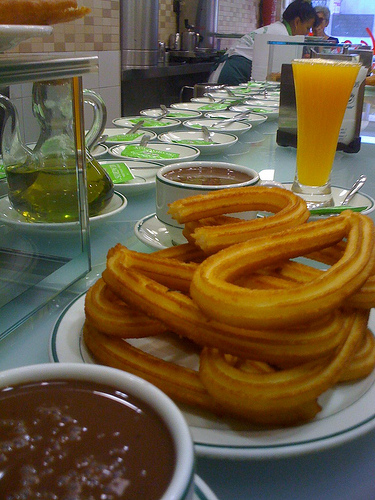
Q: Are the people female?
A: Yes, all the people are female.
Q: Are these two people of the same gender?
A: Yes, all the people are female.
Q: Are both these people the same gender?
A: Yes, all the people are female.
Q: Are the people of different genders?
A: No, all the people are female.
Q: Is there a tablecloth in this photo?
A: No, there are no tablecloths.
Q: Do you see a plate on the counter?
A: Yes, there are plates on the counter.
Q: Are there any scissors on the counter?
A: No, there are plates on the counter.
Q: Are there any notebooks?
A: No, there are no notebooks.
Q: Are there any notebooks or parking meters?
A: No, there are no notebooks or parking meters.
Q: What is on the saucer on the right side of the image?
A: The glass is on the saucer.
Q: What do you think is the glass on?
A: The glass is on the saucer.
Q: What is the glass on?
A: The glass is on the saucer.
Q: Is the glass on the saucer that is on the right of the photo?
A: Yes, the glass is on the saucer.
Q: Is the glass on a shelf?
A: No, the glass is on the saucer.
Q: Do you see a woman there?
A: Yes, there is a woman.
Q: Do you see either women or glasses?
A: Yes, there is a woman.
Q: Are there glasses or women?
A: Yes, there is a woman.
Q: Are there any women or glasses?
A: Yes, there is a woman.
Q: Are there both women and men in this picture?
A: No, there is a woman but no men.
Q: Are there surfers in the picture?
A: No, there are no surfers.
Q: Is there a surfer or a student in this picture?
A: No, there are no surfers or students.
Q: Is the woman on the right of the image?
A: Yes, the woman is on the right of the image.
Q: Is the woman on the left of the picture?
A: No, the woman is on the right of the image.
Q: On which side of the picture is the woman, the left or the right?
A: The woman is on the right of the image.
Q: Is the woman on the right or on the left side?
A: The woman is on the right of the image.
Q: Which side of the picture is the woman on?
A: The woman is on the right of the image.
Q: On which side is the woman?
A: The woman is on the right of the image.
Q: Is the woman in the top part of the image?
A: Yes, the woman is in the top of the image.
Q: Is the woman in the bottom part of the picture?
A: No, the woman is in the top of the image.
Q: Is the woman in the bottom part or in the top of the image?
A: The woman is in the top of the image.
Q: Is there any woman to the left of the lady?
A: Yes, there is a woman to the left of the lady.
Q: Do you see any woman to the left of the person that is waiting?
A: Yes, there is a woman to the left of the lady.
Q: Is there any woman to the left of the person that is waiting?
A: Yes, there is a woman to the left of the lady.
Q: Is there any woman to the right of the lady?
A: No, the woman is to the left of the lady.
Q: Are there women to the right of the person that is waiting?
A: No, the woman is to the left of the lady.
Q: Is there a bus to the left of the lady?
A: No, there is a woman to the left of the lady.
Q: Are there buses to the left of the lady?
A: No, there is a woman to the left of the lady.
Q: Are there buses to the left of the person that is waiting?
A: No, there is a woman to the left of the lady.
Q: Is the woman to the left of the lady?
A: Yes, the woman is to the left of the lady.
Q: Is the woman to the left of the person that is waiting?
A: Yes, the woman is to the left of the lady.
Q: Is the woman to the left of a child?
A: No, the woman is to the left of the lady.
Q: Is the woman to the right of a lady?
A: No, the woman is to the left of a lady.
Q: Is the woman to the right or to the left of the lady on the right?
A: The woman is to the left of the lady.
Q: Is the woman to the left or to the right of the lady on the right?
A: The woman is to the left of the lady.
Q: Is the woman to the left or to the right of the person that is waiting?
A: The woman is to the left of the lady.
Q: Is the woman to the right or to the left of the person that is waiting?
A: The woman is to the left of the lady.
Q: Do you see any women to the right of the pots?
A: Yes, there is a woman to the right of the pots.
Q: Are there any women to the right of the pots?
A: Yes, there is a woman to the right of the pots.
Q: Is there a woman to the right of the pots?
A: Yes, there is a woman to the right of the pots.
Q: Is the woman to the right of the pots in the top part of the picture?
A: Yes, the woman is to the right of the pots.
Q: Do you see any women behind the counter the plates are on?
A: Yes, there is a woman behind the counter.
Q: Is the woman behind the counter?
A: Yes, the woman is behind the counter.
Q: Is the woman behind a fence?
A: No, the woman is behind the counter.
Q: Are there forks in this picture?
A: No, there are no forks.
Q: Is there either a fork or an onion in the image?
A: No, there are no forks or onions.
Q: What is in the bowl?
A: The sauce is in the bowl.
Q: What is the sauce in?
A: The sauce is in the bowl.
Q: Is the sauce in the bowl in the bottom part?
A: Yes, the sauce is in the bowl.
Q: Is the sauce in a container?
A: No, the sauce is in the bowl.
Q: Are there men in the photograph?
A: No, there are no men.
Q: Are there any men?
A: No, there are no men.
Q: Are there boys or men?
A: No, there are no men or boys.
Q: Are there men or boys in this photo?
A: No, there are no men or boys.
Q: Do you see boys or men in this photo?
A: No, there are no men or boys.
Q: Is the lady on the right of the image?
A: Yes, the lady is on the right of the image.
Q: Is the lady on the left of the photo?
A: No, the lady is on the right of the image.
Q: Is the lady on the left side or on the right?
A: The lady is on the right of the image.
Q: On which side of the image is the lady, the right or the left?
A: The lady is on the right of the image.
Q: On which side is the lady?
A: The lady is on the right of the image.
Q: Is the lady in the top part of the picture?
A: Yes, the lady is in the top of the image.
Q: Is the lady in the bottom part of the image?
A: No, the lady is in the top of the image.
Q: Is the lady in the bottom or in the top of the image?
A: The lady is in the top of the image.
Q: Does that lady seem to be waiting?
A: Yes, the lady is waiting.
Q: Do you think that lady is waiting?
A: Yes, the lady is waiting.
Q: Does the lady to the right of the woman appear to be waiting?
A: Yes, the lady is waiting.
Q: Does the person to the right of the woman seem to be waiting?
A: Yes, the lady is waiting.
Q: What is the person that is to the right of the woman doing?
A: The lady is waiting.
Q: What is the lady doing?
A: The lady is waiting.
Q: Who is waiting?
A: The lady is waiting.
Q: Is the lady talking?
A: No, the lady is waiting.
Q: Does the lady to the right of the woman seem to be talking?
A: No, the lady is waiting.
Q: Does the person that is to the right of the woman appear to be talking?
A: No, the lady is waiting.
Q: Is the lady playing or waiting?
A: The lady is waiting.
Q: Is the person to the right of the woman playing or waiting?
A: The lady is waiting.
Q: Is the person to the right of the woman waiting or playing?
A: The lady is waiting.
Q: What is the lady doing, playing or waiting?
A: The lady is waiting.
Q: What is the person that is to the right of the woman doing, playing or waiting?
A: The lady is waiting.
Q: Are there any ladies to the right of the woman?
A: Yes, there is a lady to the right of the woman.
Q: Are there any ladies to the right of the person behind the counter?
A: Yes, there is a lady to the right of the woman.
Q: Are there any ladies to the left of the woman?
A: No, the lady is to the right of the woman.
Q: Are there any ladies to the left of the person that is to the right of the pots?
A: No, the lady is to the right of the woman.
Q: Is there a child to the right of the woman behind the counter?
A: No, there is a lady to the right of the woman.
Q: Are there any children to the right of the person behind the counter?
A: No, there is a lady to the right of the woman.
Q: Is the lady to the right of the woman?
A: Yes, the lady is to the right of the woman.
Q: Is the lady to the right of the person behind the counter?
A: Yes, the lady is to the right of the woman.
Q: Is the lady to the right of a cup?
A: No, the lady is to the right of the woman.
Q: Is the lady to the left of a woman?
A: No, the lady is to the right of a woman.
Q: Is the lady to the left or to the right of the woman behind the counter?
A: The lady is to the right of the woman.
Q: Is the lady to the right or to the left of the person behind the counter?
A: The lady is to the right of the woman.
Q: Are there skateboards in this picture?
A: No, there are no skateboards.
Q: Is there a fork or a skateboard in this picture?
A: No, there are no skateboards or forks.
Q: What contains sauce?
A: The bowl contains sauce.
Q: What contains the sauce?
A: The bowl contains sauce.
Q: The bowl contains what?
A: The bowl contains sauce.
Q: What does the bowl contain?
A: The bowl contains sauce.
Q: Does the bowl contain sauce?
A: Yes, the bowl contains sauce.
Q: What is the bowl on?
A: The bowl is on the saucer.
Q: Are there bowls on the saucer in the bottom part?
A: Yes, there is a bowl on the saucer.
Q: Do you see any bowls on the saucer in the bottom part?
A: Yes, there is a bowl on the saucer.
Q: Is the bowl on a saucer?
A: Yes, the bowl is on a saucer.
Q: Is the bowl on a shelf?
A: No, the bowl is on a saucer.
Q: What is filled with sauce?
A: The bowl is filled with sauce.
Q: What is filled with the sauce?
A: The bowl is filled with sauce.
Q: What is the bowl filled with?
A: The bowl is filled with sauce.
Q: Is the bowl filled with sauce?
A: Yes, the bowl is filled with sauce.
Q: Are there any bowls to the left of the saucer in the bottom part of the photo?
A: Yes, there is a bowl to the left of the saucer.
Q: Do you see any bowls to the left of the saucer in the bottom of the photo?
A: Yes, there is a bowl to the left of the saucer.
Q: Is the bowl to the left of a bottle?
A: No, the bowl is to the left of the saucer.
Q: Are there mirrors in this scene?
A: No, there are no mirrors.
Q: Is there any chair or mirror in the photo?
A: No, there are no mirrors or chairs.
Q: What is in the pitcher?
A: The oil is in the pitcher.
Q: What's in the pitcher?
A: The oil is in the pitcher.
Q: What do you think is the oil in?
A: The oil is in the pitcher.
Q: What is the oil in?
A: The oil is in the pitcher.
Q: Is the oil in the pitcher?
A: Yes, the oil is in the pitcher.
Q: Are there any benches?
A: No, there are no benches.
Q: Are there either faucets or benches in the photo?
A: No, there are no benches or faucets.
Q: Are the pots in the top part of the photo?
A: Yes, the pots are in the top of the image.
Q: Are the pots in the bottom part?
A: No, the pots are in the top of the image.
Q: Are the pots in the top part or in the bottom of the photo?
A: The pots are in the top of the image.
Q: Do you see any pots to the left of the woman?
A: Yes, there are pots to the left of the woman.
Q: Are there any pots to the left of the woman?
A: Yes, there are pots to the left of the woman.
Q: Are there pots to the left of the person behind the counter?
A: Yes, there are pots to the left of the woman.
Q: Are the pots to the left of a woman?
A: Yes, the pots are to the left of a woman.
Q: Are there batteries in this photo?
A: No, there are no batteries.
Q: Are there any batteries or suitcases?
A: No, there are no batteries or suitcases.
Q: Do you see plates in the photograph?
A: Yes, there is a plate.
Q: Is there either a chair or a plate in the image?
A: Yes, there is a plate.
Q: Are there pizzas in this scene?
A: No, there are no pizzas.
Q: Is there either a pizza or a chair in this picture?
A: No, there are no pizzas or chairs.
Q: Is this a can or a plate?
A: This is a plate.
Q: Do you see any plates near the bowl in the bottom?
A: Yes, there is a plate near the bowl.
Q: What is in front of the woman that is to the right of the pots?
A: The counter is in front of the woman.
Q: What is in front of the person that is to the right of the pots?
A: The counter is in front of the woman.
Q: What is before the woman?
A: The counter is in front of the woman.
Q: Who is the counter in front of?
A: The counter is in front of the woman.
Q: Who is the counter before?
A: The counter is in front of the woman.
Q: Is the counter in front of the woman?
A: Yes, the counter is in front of the woman.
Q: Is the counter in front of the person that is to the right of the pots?
A: Yes, the counter is in front of the woman.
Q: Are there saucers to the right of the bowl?
A: Yes, there is a saucer to the right of the bowl.